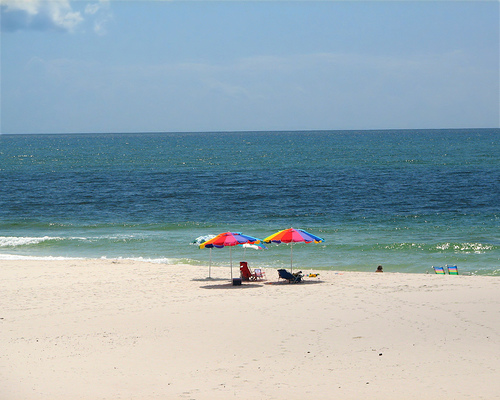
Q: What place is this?
A: It is an ocean.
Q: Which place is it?
A: It is an ocean.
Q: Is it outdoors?
A: Yes, it is outdoors.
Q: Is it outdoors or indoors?
A: It is outdoors.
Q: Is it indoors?
A: No, it is outdoors.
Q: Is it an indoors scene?
A: No, it is outdoors.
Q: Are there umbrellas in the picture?
A: Yes, there is an umbrella.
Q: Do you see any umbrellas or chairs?
A: Yes, there is an umbrella.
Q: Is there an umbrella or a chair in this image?
A: Yes, there is an umbrella.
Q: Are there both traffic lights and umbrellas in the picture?
A: No, there is an umbrella but no traffic lights.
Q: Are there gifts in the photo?
A: No, there are no gifts.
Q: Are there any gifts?
A: No, there are no gifts.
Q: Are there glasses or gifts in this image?
A: No, there are no gifts or glasses.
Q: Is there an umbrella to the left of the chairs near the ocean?
A: Yes, there is an umbrella to the left of the chairs.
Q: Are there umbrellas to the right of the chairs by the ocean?
A: No, the umbrella is to the left of the chairs.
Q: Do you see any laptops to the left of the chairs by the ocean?
A: No, there is an umbrella to the left of the chairs.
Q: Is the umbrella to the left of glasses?
A: No, the umbrella is to the left of the chairs.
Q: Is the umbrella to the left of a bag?
A: No, the umbrella is to the left of the chair.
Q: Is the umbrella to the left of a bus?
A: No, the umbrella is to the left of the chair.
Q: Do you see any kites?
A: No, there are no kites.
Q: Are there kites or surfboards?
A: No, there are no kites or surfboards.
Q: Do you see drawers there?
A: No, there are no drawers.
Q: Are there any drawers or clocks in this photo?
A: No, there are no drawers or clocks.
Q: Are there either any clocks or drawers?
A: No, there are no drawers or clocks.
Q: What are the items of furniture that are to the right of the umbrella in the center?
A: The pieces of furniture are chairs.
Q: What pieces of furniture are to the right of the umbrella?
A: The pieces of furniture are chairs.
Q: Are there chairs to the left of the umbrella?
A: No, the chairs are to the right of the umbrella.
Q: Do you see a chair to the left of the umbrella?
A: No, the chairs are to the right of the umbrella.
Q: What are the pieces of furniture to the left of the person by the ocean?
A: The pieces of furniture are chairs.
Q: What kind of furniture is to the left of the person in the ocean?
A: The pieces of furniture are chairs.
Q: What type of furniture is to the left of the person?
A: The pieces of furniture are chairs.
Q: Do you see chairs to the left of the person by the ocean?
A: Yes, there are chairs to the left of the person.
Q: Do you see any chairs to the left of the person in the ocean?
A: Yes, there are chairs to the left of the person.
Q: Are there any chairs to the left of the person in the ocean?
A: Yes, there are chairs to the left of the person.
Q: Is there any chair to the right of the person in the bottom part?
A: No, the chairs are to the left of the person.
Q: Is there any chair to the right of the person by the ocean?
A: No, the chairs are to the left of the person.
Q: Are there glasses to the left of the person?
A: No, there are chairs to the left of the person.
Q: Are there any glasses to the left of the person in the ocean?
A: No, there are chairs to the left of the person.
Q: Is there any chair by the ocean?
A: Yes, there are chairs by the ocean.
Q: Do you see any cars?
A: No, there are no cars.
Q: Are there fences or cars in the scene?
A: No, there are no cars or fences.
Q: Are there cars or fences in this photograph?
A: No, there are no cars or fences.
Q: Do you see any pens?
A: No, there are no pens.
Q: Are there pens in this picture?
A: No, there are no pens.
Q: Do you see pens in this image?
A: No, there are no pens.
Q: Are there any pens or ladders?
A: No, there are no pens or ladders.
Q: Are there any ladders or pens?
A: No, there are no pens or ladders.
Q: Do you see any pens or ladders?
A: No, there are no pens or ladders.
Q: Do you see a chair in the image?
A: Yes, there is a chair.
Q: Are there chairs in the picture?
A: Yes, there is a chair.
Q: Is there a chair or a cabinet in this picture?
A: Yes, there is a chair.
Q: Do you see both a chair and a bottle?
A: No, there is a chair but no bottles.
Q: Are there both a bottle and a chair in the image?
A: No, there is a chair but no bottles.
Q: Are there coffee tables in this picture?
A: No, there are no coffee tables.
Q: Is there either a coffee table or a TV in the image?
A: No, there are no coffee tables or televisions.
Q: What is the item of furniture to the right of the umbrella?
A: The piece of furniture is a chair.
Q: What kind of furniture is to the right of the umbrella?
A: The piece of furniture is a chair.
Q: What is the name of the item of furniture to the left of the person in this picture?
A: The piece of furniture is a chair.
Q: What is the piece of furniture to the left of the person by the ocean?
A: The piece of furniture is a chair.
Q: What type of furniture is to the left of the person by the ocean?
A: The piece of furniture is a chair.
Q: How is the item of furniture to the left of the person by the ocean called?
A: The piece of furniture is a chair.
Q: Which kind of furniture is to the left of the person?
A: The piece of furniture is a chair.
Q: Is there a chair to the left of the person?
A: Yes, there is a chair to the left of the person.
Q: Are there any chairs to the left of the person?
A: Yes, there is a chair to the left of the person.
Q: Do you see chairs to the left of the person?
A: Yes, there is a chair to the left of the person.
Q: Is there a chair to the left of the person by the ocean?
A: Yes, there is a chair to the left of the person.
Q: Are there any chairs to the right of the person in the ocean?
A: No, the chair is to the left of the person.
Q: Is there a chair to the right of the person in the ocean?
A: No, the chair is to the left of the person.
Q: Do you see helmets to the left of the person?
A: No, there is a chair to the left of the person.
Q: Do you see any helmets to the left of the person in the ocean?
A: No, there is a chair to the left of the person.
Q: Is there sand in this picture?
A: Yes, there is sand.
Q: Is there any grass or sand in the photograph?
A: Yes, there is sand.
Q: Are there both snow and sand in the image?
A: No, there is sand but no snow.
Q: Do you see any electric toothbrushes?
A: No, there are no electric toothbrushes.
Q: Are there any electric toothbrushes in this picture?
A: No, there are no electric toothbrushes.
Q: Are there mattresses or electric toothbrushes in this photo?
A: No, there are no electric toothbrushes or mattresses.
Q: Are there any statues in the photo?
A: No, there are no statues.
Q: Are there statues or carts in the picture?
A: No, there are no statues or carts.